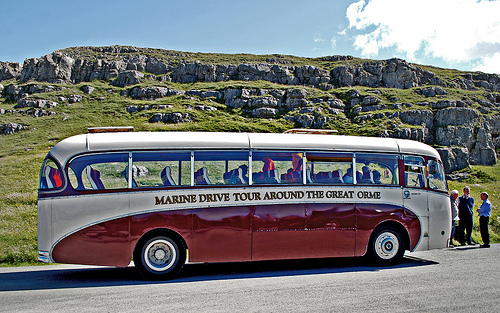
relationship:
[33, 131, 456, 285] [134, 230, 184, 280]
bus has wheel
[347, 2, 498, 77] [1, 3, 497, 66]
clouds are in sky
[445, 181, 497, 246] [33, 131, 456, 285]
people next to bus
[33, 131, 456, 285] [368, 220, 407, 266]
bus has tire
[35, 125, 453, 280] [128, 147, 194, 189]
bus has window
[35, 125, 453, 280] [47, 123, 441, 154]
bus has roof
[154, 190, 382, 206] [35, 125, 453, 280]
text are on side of bus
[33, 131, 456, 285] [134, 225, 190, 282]
bus has tire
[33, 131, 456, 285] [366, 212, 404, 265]
bus has tire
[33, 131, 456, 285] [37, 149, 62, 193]
bus has window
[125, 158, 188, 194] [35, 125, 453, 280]
window on bus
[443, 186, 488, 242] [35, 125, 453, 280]
man by bus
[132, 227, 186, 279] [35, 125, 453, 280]
tire on bus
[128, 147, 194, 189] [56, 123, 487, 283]
window on bus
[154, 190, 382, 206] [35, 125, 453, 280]
text on bus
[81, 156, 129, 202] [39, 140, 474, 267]
seats on bus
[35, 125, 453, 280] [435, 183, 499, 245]
bus by people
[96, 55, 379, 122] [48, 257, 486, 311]
landscape by road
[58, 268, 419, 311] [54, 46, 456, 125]
road by landscape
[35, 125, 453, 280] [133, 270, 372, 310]
bus by road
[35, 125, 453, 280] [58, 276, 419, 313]
bus by road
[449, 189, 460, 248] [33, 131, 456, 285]
people standing in front of bus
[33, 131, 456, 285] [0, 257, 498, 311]
bus parked in street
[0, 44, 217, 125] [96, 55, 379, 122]
hills cover with landscape